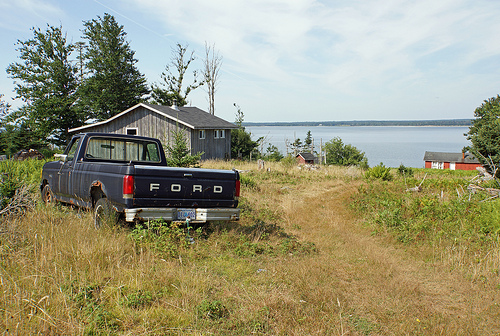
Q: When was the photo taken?
A: During the day.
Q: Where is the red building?
A: By the water.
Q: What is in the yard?
A: A truck.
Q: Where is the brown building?
A: On the left.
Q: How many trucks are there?
A: One.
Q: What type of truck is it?
A: Ford.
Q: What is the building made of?
A: Wood.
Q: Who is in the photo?
A: No one.